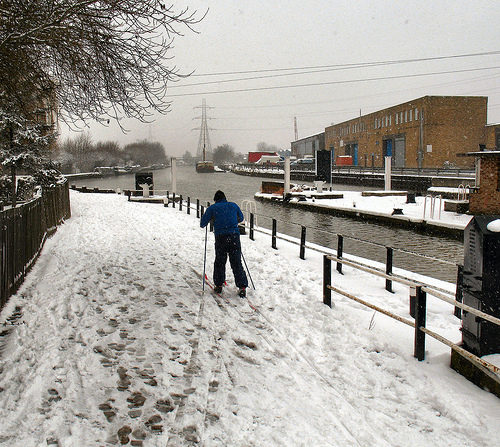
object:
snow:
[2, 328, 176, 441]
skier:
[199, 189, 249, 297]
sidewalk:
[2, 182, 497, 446]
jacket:
[200, 200, 244, 235]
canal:
[68, 149, 465, 287]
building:
[322, 94, 486, 175]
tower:
[191, 98, 217, 164]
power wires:
[123, 50, 500, 102]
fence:
[0, 175, 70, 319]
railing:
[227, 164, 477, 181]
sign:
[427, 144, 432, 152]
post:
[413, 284, 426, 362]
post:
[322, 254, 332, 309]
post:
[386, 247, 393, 292]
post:
[453, 262, 464, 320]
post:
[300, 226, 306, 260]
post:
[272, 218, 277, 248]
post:
[250, 213, 254, 240]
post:
[196, 199, 199, 218]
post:
[186, 195, 191, 214]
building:
[459, 148, 499, 214]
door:
[354, 144, 358, 165]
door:
[386, 139, 393, 168]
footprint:
[98, 401, 117, 419]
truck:
[248, 151, 285, 165]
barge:
[196, 161, 214, 172]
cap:
[213, 190, 227, 201]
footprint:
[116, 424, 133, 444]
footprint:
[148, 412, 165, 434]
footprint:
[126, 394, 145, 422]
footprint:
[46, 386, 64, 405]